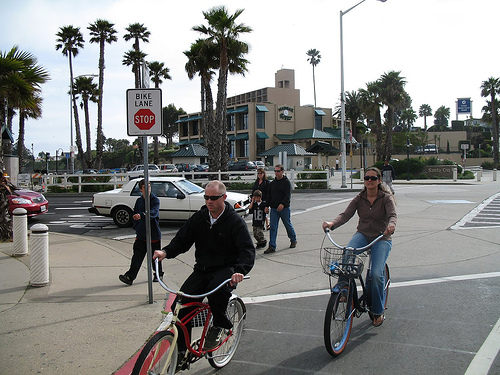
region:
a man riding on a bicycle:
[98, 173, 265, 358]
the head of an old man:
[194, 173, 226, 220]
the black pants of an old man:
[168, 276, 221, 338]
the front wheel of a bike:
[136, 313, 187, 366]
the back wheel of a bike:
[203, 296, 254, 358]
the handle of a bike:
[143, 257, 224, 296]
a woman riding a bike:
[345, 160, 415, 260]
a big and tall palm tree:
[179, 10, 245, 175]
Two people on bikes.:
[132, 167, 400, 374]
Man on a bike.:
[134, 180, 261, 372]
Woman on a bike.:
[315, 165, 399, 357]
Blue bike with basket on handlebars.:
[316, 222, 391, 354]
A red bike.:
[132, 257, 252, 374]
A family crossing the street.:
[250, 162, 299, 254]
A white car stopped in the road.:
[90, 172, 255, 219]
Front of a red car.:
[4, 184, 51, 221]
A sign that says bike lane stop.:
[122, 85, 166, 306]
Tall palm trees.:
[182, 0, 243, 180]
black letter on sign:
[135, 92, 140, 100]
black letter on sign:
[139, 92, 144, 99]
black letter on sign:
[143, 90, 146, 100]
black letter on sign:
[147, 90, 152, 100]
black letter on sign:
[133, 98, 140, 108]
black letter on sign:
[138, 100, 144, 107]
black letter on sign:
[143, 98, 148, 107]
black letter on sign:
[146, 98, 154, 108]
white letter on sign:
[133, 113, 140, 124]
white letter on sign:
[142, 113, 150, 125]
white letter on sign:
[148, 113, 155, 125]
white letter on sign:
[143, 114, 149, 124]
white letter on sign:
[138, 113, 143, 123]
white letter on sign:
[133, 113, 140, 126]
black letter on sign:
[134, 90, 141, 102]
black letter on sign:
[139, 90, 149, 101]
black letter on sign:
[146, 90, 153, 102]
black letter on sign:
[137, 99, 146, 110]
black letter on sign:
[141, 98, 150, 108]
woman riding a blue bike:
[315, 149, 409, 356]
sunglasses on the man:
[200, 185, 225, 210]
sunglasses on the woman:
[354, 170, 383, 190]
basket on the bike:
[322, 238, 367, 285]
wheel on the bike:
[316, 273, 358, 356]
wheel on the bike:
[129, 325, 175, 373]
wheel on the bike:
[205, 298, 246, 363]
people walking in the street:
[244, 158, 298, 252]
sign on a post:
[120, 85, 162, 138]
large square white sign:
[126, 89, 166, 138]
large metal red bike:
[129, 256, 246, 373]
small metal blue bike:
[320, 230, 393, 357]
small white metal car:
[89, 176, 251, 229]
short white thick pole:
[27, 223, 49, 289]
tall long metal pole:
[143, 136, 155, 305]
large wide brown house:
[174, 68, 499, 177]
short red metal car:
[0, 179, 51, 223]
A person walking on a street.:
[246, 189, 271, 249]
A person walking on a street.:
[266, 164, 298, 251]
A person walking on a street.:
[251, 166, 271, 231]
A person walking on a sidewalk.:
[118, 179, 163, 285]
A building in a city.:
[178, 66, 352, 161]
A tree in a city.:
[55, 21, 89, 173]